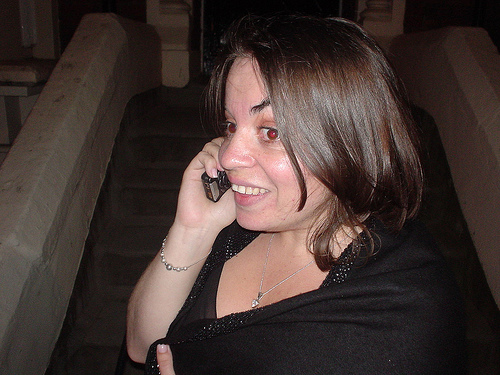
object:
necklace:
[243, 231, 335, 310]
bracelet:
[159, 234, 212, 270]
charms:
[164, 263, 174, 270]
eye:
[256, 122, 281, 142]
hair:
[205, 13, 434, 270]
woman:
[126, 15, 464, 375]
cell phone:
[200, 160, 239, 201]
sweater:
[115, 219, 462, 375]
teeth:
[226, 184, 269, 197]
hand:
[174, 137, 240, 240]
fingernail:
[156, 344, 169, 353]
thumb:
[155, 343, 176, 374]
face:
[217, 57, 324, 231]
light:
[272, 71, 419, 187]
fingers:
[192, 150, 219, 181]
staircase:
[4, 13, 498, 373]